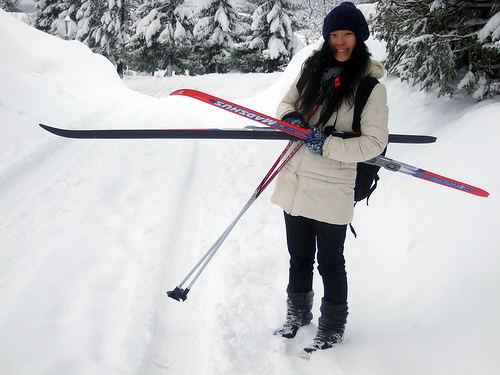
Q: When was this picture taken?
A: Daytime.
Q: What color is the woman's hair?
A: Black.